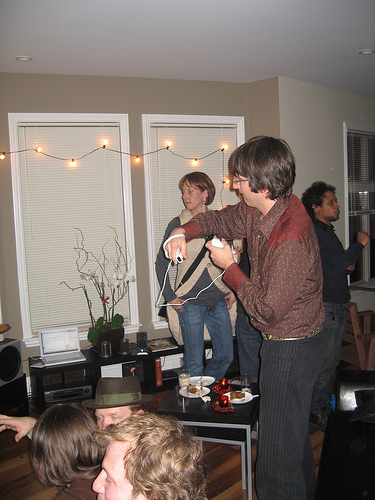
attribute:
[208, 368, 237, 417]
candles — red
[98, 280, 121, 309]
bow — red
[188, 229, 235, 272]
controller — game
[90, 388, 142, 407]
band — green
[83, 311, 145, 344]
leaves — green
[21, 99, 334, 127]
lights — lit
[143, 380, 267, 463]
table — small, black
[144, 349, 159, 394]
book — red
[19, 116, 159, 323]
blinds — closed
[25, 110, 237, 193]
lights — white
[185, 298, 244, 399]
jeans — blue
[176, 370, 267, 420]
plates — white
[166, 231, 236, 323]
purse — black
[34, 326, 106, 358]
laptop — open, white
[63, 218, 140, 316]
branches — bare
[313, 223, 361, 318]
shirt — gray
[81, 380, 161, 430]
hat — brown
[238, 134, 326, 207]
hair — brown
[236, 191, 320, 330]
shirt — red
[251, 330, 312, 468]
pants — black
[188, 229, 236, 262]
remote — wii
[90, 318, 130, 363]
pot — black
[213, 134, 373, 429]
man — playing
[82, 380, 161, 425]
fedora — green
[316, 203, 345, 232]
hair — curly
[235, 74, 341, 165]
walls — beige